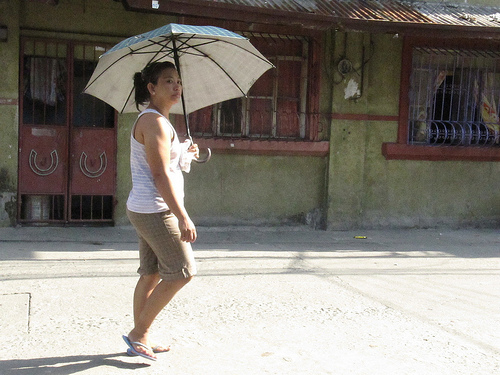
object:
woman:
[120, 59, 205, 361]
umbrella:
[79, 22, 281, 163]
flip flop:
[118, 334, 160, 362]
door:
[16, 36, 120, 231]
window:
[178, 19, 329, 158]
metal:
[188, 33, 307, 136]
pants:
[124, 202, 198, 281]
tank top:
[123, 108, 185, 217]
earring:
[151, 90, 158, 98]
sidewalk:
[1, 227, 500, 375]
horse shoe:
[77, 149, 109, 180]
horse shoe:
[28, 148, 58, 175]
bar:
[442, 54, 462, 144]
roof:
[138, 0, 499, 38]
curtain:
[408, 52, 499, 143]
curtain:
[23, 56, 69, 107]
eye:
[166, 78, 172, 85]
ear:
[146, 81, 157, 97]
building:
[2, 1, 499, 229]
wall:
[1, 0, 498, 226]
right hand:
[177, 218, 200, 244]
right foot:
[126, 331, 157, 359]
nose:
[174, 85, 181, 93]